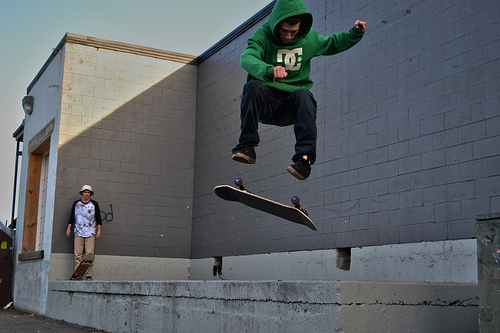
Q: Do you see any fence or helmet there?
A: No, there are no fences or helmets.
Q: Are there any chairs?
A: No, there are no chairs.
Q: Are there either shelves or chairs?
A: No, there are no chairs or shelves.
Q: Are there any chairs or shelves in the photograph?
A: No, there are no chairs or shelves.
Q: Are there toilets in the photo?
A: No, there are no toilets.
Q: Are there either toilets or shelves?
A: No, there are no toilets or shelves.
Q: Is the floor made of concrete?
A: Yes, the floor is made of concrete.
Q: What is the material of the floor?
A: The floor is made of cement.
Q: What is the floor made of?
A: The floor is made of concrete.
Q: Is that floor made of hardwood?
A: No, the floor is made of concrete.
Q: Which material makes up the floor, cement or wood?
A: The floor is made of cement.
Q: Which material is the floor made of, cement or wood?
A: The floor is made of cement.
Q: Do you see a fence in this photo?
A: No, there are no fences.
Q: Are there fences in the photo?
A: No, there are no fences.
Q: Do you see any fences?
A: No, there are no fences.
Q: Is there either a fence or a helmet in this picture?
A: No, there are no fences or helmets.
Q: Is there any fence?
A: No, there are no fences.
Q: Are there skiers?
A: No, there are no skiers.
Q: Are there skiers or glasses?
A: No, there are no skiers or glasses.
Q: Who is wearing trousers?
A: The man is wearing trousers.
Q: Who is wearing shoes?
A: The man is wearing shoes.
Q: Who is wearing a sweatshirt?
A: The man is wearing a sweatshirt.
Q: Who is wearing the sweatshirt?
A: The man is wearing a sweatshirt.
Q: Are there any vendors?
A: No, there are no vendors.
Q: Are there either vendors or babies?
A: No, there are no vendors or babies.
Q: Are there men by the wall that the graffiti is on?
A: Yes, there is a man by the wall.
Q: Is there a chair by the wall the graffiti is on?
A: No, there is a man by the wall.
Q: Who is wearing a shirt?
A: The man is wearing a shirt.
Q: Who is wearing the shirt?
A: The man is wearing a shirt.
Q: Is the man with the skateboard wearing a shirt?
A: Yes, the man is wearing a shirt.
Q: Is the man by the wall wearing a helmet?
A: No, the man is wearing a shirt.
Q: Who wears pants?
A: The man wears pants.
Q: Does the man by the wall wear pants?
A: Yes, the man wears pants.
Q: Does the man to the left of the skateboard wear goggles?
A: No, the man wears pants.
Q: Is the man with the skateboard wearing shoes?
A: Yes, the man is wearing shoes.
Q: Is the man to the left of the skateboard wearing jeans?
A: No, the man is wearing shoes.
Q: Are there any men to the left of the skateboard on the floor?
A: Yes, there is a man to the left of the skateboard.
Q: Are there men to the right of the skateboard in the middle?
A: No, the man is to the left of the skateboard.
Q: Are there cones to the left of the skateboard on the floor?
A: No, there is a man to the left of the skateboard.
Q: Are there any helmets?
A: No, there are no helmets.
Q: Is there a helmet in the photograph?
A: No, there are no helmets.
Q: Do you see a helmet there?
A: No, there are no helmets.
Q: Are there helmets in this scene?
A: No, there are no helmets.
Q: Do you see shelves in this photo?
A: No, there are no shelves.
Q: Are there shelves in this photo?
A: No, there are no shelves.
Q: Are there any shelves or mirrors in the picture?
A: No, there are no shelves or mirrors.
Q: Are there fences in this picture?
A: No, there are no fences.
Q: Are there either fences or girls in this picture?
A: No, there are no fences or girls.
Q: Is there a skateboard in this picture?
A: Yes, there is a skateboard.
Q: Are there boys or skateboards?
A: Yes, there is a skateboard.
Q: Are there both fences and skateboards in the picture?
A: No, there is a skateboard but no fences.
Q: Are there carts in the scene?
A: No, there are no carts.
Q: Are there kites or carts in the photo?
A: No, there are no carts or kites.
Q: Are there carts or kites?
A: No, there are no carts or kites.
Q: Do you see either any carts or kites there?
A: No, there are no carts or kites.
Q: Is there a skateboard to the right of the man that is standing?
A: Yes, there is a skateboard to the right of the man.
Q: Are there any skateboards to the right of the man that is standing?
A: Yes, there is a skateboard to the right of the man.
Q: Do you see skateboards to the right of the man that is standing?
A: Yes, there is a skateboard to the right of the man.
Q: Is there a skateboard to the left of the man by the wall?
A: No, the skateboard is to the right of the man.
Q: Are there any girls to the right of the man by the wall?
A: No, there is a skateboard to the right of the man.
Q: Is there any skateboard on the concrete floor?
A: Yes, there is a skateboard on the floor.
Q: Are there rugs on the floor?
A: No, there is a skateboard on the floor.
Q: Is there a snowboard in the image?
A: No, there are no snowboards.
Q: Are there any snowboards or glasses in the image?
A: No, there are no snowboards or glasses.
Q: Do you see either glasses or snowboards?
A: No, there are no snowboards or glasses.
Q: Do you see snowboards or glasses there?
A: No, there are no snowboards or glasses.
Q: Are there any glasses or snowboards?
A: No, there are no snowboards or glasses.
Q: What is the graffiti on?
A: The graffiti is on the wall.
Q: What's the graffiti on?
A: The graffiti is on the wall.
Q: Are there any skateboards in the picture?
A: Yes, there is a skateboard.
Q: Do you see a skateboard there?
A: Yes, there is a skateboard.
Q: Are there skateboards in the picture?
A: Yes, there is a skateboard.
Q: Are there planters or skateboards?
A: Yes, there is a skateboard.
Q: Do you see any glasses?
A: No, there are no glasses.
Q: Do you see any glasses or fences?
A: No, there are no glasses or fences.